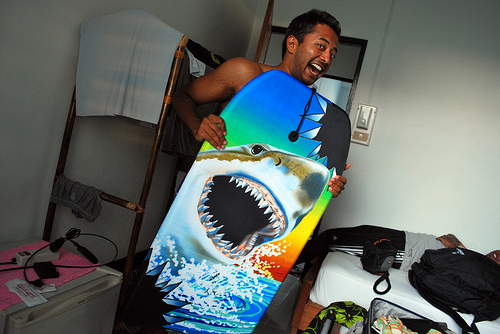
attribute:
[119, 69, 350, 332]
surfboard — colorful, foam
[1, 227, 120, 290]
cord — black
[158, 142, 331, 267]
shark — existing, drawn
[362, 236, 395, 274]
camera — black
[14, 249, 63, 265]
power strip — white, existing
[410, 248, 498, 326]
backpack — black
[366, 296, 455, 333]
suitcase — open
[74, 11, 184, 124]
towel — white